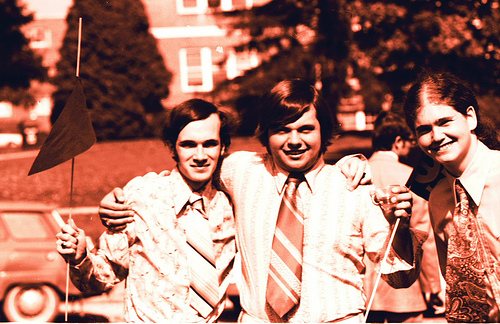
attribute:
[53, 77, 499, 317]
friends — smiling, three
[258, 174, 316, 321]
ties — striped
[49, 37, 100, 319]
flag — triangular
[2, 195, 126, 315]
wagon — old, parked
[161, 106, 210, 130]
hair — black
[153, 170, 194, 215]
collar — long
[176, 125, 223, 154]
eyes — squinty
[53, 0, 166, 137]
tree — tall